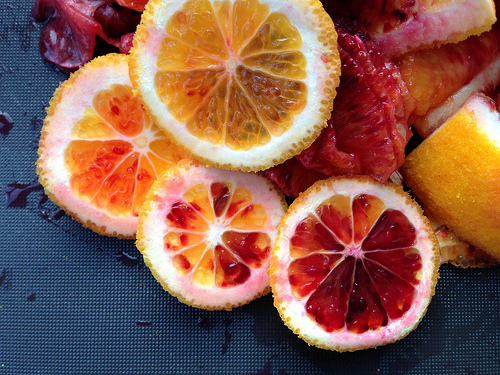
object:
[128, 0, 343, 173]
lemon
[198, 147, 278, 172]
peel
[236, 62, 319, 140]
slice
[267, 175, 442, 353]
orange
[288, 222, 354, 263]
section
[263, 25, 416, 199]
fruit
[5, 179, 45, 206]
juice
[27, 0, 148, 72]
strawerries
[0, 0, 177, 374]
cloth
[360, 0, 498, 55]
pomegranets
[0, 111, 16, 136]
drop